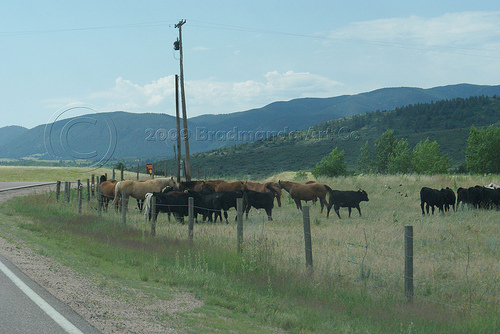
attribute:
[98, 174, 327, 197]
horse — in the field, brown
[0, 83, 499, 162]
mountains — in the distance., in the distance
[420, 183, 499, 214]
cows — eating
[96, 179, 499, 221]
livestock — eating, in pasture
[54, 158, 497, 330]
fence — wire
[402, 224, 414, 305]
pole — wood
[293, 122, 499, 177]
trees — green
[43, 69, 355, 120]
cloud — fluffy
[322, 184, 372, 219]
cow — walking, black